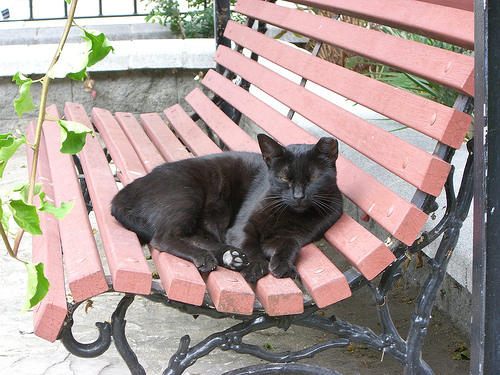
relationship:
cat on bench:
[104, 133, 346, 280] [24, 1, 496, 373]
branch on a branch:
[0, 0, 114, 310] [0, 0, 114, 310]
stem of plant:
[26, 1, 67, 256] [23, 3, 48, 230]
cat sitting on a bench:
[109, 133, 346, 286] [22, 40, 487, 307]